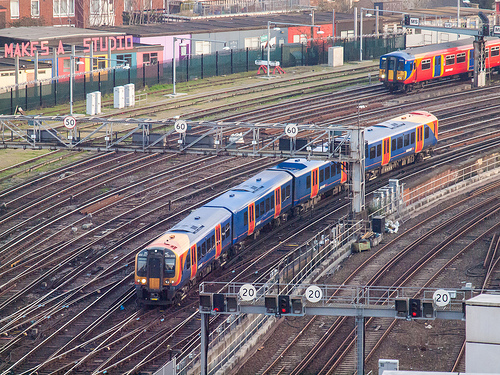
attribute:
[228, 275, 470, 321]
signs — round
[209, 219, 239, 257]
doors — orange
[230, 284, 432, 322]
lights — glowing, red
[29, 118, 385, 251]
frame — metal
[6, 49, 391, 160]
fence — metal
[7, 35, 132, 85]
letters — red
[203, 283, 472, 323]
lights — red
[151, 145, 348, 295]
train — blue, red, yellow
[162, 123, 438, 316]
train — blue, red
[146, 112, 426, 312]
train — red, blue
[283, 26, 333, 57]
building — red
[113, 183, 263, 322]
engine — orange, blue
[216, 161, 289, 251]
car — blue, orange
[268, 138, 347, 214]
car — orange, blue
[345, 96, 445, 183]
car — blue, orange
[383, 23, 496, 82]
engine — orange, red, blue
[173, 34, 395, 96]
fence — long, green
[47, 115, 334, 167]
signal — electronic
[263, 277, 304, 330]
signal — electronic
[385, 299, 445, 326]
signal — electronic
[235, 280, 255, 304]
sign — white, round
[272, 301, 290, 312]
light — red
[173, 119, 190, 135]
number — 60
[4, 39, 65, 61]
letters — red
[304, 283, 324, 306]
sign — 20